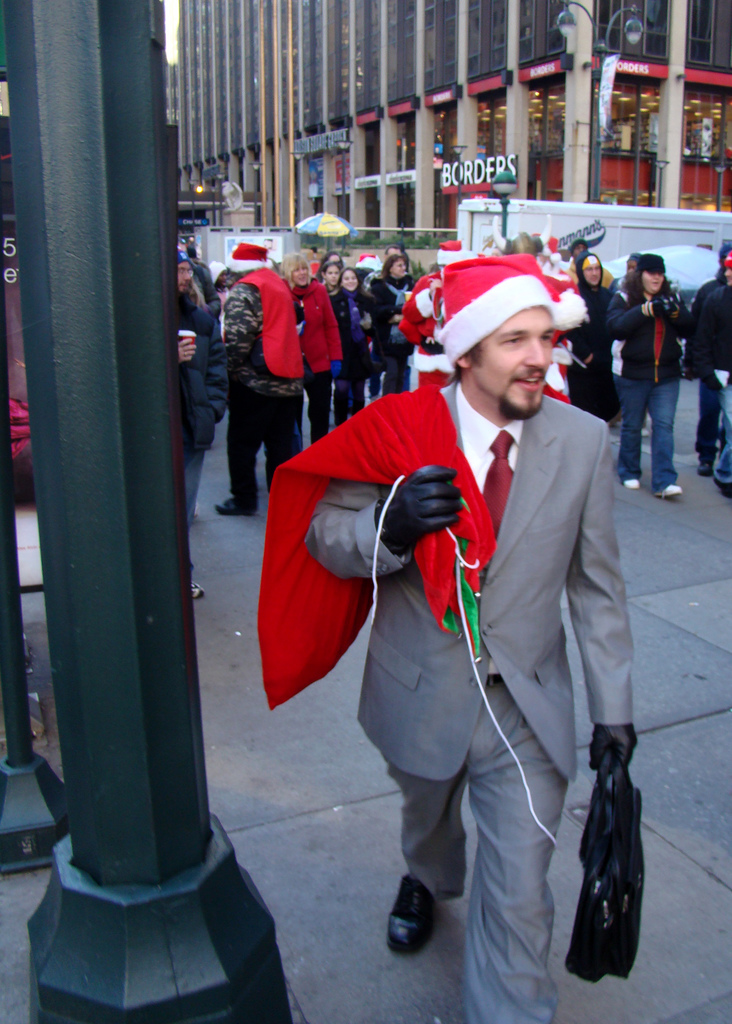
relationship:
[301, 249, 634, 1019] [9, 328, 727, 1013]
man on sidewalk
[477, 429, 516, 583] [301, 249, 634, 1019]
tie on man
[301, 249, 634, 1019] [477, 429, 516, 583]
man with tie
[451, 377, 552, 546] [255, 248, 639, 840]
shirt on man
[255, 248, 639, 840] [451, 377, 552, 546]
man wearing shirt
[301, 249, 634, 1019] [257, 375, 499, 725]
man holding bag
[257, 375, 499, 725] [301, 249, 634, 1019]
bag with man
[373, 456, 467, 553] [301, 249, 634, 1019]
glove on man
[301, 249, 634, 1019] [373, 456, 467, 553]
man with glove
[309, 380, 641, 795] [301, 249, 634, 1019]
jacket on man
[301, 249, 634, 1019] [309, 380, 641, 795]
man wearing jacket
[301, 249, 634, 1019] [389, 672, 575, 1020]
man wearing pants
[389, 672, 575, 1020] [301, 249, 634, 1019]
pants on man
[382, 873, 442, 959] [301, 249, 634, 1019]
shoe on man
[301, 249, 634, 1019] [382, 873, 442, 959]
man wearing shoe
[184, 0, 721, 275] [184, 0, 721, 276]
building beside building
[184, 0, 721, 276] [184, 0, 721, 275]
building against building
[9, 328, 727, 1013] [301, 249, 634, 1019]
sidewalk under man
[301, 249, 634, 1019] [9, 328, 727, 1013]
man walking on sidewalk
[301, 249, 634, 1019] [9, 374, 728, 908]
man walking on sidewalk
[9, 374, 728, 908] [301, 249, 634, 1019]
sidewalk under man